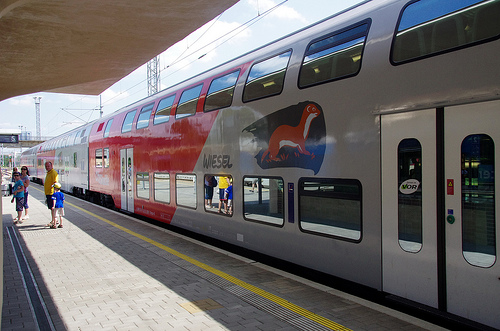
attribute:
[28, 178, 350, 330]
line — yellow, long, white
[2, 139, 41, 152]
bridge — white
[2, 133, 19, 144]
sign — black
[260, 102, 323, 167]
animal — red, white, ferret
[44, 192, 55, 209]
shorts — black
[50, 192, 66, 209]
shirt — blue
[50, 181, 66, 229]
boy — little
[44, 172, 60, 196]
shirt — yellow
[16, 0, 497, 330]
train — big, double decker, red, silver, long